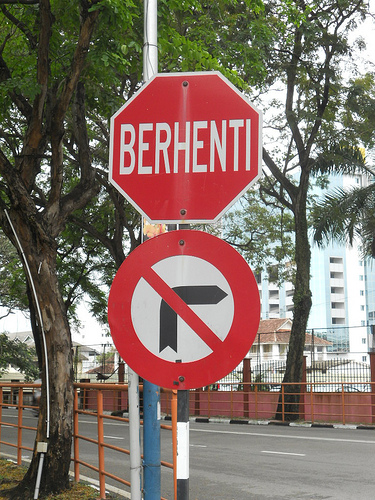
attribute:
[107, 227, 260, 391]
sign — round, red, white, black, prohibitive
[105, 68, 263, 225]
sign — octagon, red, white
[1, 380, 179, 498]
fence — orange, metal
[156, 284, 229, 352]
arrow — black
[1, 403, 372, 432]
curb — black, white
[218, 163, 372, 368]
building — tall, blue, apartments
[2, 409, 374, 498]
road — paved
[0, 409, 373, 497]
street — paved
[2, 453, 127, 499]
grass — green, minimal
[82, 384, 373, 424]
wall — red, solid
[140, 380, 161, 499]
pole section — blue, metal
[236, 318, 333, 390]
house — white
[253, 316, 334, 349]
roof — red, shingled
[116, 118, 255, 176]
letters — white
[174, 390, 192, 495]
pole — white, black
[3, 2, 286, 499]
tree — brown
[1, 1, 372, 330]
leaves — green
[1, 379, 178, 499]
gate — orange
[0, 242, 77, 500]
trunk — curved